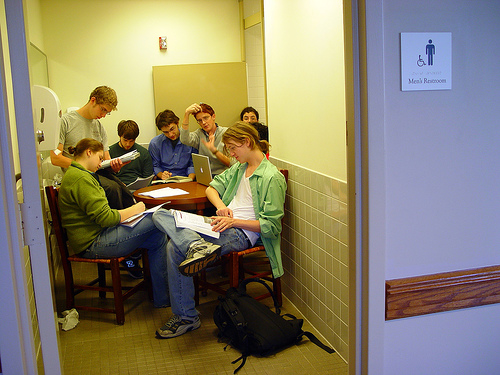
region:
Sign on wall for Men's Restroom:
[399, 22, 458, 102]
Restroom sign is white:
[400, 25, 466, 105]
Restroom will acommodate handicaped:
[398, 25, 465, 103]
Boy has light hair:
[81, 77, 123, 107]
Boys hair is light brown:
[86, 80, 123, 110]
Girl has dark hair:
[67, 130, 109, 163]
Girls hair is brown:
[64, 134, 102, 164]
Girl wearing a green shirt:
[48, 152, 128, 254]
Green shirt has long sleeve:
[60, 168, 137, 233]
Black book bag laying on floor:
[207, 266, 329, 371]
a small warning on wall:
[392, 19, 458, 104]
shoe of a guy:
[149, 320, 216, 342]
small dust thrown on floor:
[55, 292, 86, 344]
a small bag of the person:
[208, 269, 328, 367]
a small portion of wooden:
[374, 260, 499, 323]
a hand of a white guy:
[186, 99, 208, 128]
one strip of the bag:
[246, 278, 292, 314]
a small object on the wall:
[142, 25, 174, 55]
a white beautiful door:
[371, 4, 498, 374]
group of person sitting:
[11, 69, 330, 339]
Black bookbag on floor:
[206, 285, 341, 373]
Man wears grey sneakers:
[173, 237, 225, 277]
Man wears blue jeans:
[163, 247, 183, 314]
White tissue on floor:
[56, 305, 83, 334]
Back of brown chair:
[44, 185, 63, 248]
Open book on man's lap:
[169, 205, 226, 237]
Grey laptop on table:
[186, 147, 216, 188]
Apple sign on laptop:
[196, 162, 210, 175]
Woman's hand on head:
[180, 93, 220, 148]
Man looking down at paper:
[153, 104, 191, 188]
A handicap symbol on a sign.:
[412, 49, 427, 71]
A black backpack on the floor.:
[201, 279, 338, 372]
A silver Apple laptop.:
[187, 153, 239, 193]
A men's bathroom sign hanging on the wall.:
[392, 29, 462, 99]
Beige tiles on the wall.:
[266, 157, 364, 363]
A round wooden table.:
[132, 171, 218, 295]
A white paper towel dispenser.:
[30, 86, 71, 161]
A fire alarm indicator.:
[155, 35, 177, 57]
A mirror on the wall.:
[27, 43, 57, 178]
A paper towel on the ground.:
[52, 306, 89, 347]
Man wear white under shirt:
[238, 182, 252, 217]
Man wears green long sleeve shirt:
[257, 159, 284, 249]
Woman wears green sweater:
[64, 171, 96, 232]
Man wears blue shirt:
[150, 143, 191, 166]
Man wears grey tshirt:
[65, 112, 84, 142]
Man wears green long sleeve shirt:
[140, 149, 153, 173]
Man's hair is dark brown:
[153, 108, 178, 125]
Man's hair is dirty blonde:
[226, 123, 257, 141]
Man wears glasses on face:
[193, 110, 215, 124]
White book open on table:
[133, 182, 192, 204]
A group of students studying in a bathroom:
[48, 78, 301, 345]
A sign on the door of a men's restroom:
[396, 29, 456, 91]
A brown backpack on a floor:
[213, 278, 313, 358]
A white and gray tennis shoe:
[178, 239, 219, 274]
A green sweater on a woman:
[56, 161, 126, 253]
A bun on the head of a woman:
[62, 142, 79, 157]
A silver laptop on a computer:
[191, 148, 216, 188]